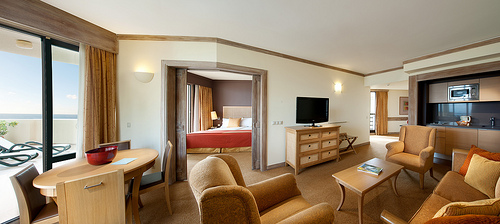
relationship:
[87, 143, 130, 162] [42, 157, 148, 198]
bowl on table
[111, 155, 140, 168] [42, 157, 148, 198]
paper on table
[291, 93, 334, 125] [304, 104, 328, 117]
t.v. has screen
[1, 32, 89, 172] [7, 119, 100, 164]
window shows deck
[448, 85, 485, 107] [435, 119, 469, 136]
microwave above sink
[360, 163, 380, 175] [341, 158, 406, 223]
book on coffee-table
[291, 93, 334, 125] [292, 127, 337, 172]
t.v. on chest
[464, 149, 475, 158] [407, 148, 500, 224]
pillow on couch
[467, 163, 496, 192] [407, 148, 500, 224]
pillow on couch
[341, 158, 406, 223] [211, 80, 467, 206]
coffee-table in livingroom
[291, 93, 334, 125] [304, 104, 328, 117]
television has screen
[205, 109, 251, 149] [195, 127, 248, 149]
bed has cover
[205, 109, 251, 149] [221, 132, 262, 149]
bed has sheets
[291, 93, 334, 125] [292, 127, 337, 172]
television on chest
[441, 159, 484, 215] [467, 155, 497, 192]
couch has pillow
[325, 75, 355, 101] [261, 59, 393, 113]
light-fixture on wall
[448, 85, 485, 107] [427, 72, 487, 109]
microwave in wall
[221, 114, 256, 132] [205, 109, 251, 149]
pillow on bed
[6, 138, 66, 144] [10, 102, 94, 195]
chair on patio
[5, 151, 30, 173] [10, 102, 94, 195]
chair on patio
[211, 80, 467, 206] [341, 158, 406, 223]
livingroom has coffee-table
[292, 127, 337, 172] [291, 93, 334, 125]
chest holding television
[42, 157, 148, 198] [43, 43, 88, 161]
table by door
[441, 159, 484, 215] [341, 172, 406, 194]
love-seat by coffee-table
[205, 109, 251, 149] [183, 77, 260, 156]
bed in bedroom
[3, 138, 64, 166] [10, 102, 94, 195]
chaise-lounge on patio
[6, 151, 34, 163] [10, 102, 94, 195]
chaise-lounge on patio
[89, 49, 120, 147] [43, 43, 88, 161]
drapes over door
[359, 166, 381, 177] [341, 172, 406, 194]
book on coffee-table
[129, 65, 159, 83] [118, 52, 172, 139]
light on wall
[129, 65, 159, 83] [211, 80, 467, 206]
light in livingroom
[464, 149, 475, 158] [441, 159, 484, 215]
pillow on couch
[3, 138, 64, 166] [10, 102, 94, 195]
chair on patio